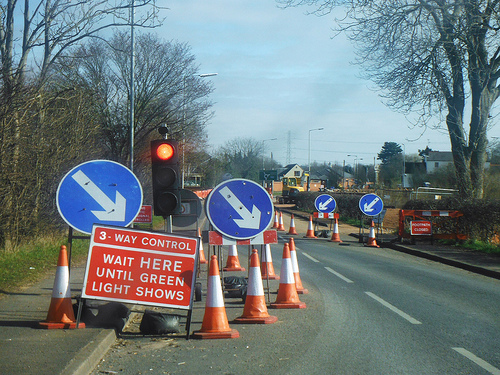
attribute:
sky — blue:
[4, 5, 498, 168]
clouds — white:
[307, 92, 422, 150]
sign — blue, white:
[205, 178, 282, 241]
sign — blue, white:
[55, 157, 142, 233]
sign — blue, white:
[359, 190, 388, 218]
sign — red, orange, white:
[85, 229, 204, 317]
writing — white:
[96, 249, 187, 307]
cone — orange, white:
[196, 256, 240, 339]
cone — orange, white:
[41, 242, 88, 330]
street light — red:
[150, 136, 184, 215]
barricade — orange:
[394, 200, 470, 248]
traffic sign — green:
[257, 167, 280, 182]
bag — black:
[138, 314, 184, 338]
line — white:
[297, 238, 433, 340]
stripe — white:
[202, 273, 226, 308]